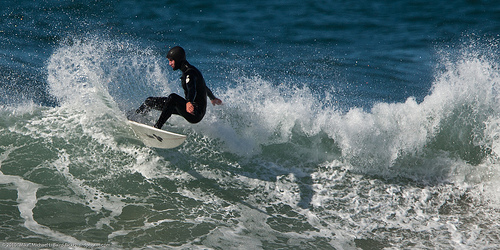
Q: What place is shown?
A: It is an ocean.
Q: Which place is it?
A: It is an ocean.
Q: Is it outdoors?
A: Yes, it is outdoors.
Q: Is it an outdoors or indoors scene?
A: It is outdoors.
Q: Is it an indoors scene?
A: No, it is outdoors.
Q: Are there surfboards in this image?
A: Yes, there is a surfboard.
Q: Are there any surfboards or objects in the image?
A: Yes, there is a surfboard.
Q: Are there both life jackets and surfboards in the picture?
A: No, there is a surfboard but no life jackets.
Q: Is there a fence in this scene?
A: No, there are no fences.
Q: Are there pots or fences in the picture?
A: No, there are no fences or pots.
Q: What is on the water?
A: The surfboard is on the water.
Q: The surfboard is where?
A: The surfboard is on the water.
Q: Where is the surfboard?
A: The surfboard is on the water.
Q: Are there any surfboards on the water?
A: Yes, there is a surfboard on the water.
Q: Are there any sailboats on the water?
A: No, there is a surfboard on the water.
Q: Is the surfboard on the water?
A: Yes, the surfboard is on the water.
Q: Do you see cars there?
A: No, there are no cars.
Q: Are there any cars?
A: No, there are no cars.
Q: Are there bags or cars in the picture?
A: No, there are no cars or bags.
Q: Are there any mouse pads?
A: No, there are no mouse pads.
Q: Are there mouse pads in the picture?
A: No, there are no mouse pads.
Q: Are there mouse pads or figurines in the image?
A: No, there are no mouse pads or figurines.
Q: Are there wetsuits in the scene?
A: Yes, there is a wetsuit.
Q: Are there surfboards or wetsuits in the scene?
A: Yes, there is a wetsuit.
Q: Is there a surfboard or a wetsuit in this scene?
A: Yes, there is a wetsuit.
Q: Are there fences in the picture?
A: No, there are no fences.